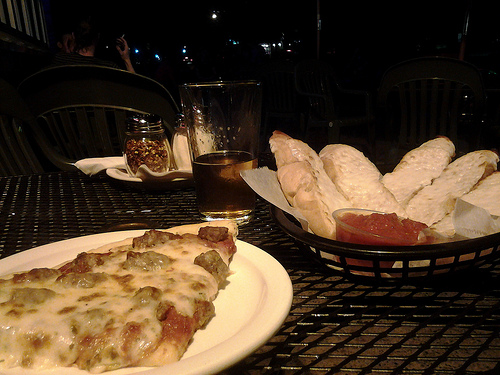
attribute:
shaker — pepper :
[120, 110, 171, 184]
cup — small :
[330, 203, 430, 274]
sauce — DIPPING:
[329, 207, 439, 246]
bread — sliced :
[272, 133, 498, 235]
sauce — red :
[329, 206, 429, 273]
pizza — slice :
[7, 216, 247, 373]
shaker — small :
[127, 116, 177, 183]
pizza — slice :
[10, 242, 232, 364]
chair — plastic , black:
[282, 70, 392, 164]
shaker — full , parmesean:
[167, 99, 221, 179]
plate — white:
[251, 301, 278, 333]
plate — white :
[0, 229, 295, 373]